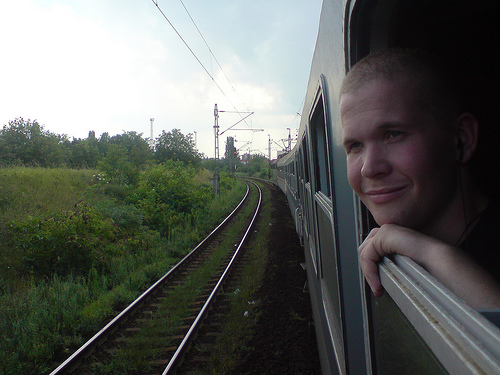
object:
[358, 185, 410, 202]
mouth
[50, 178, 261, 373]
railway line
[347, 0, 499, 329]
frame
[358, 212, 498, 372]
ledge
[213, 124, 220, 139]
part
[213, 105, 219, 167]
pole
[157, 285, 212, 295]
rail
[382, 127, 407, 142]
eye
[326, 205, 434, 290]
an hand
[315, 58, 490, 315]
person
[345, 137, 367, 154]
eye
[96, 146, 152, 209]
bush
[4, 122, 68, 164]
bush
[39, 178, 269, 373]
tracks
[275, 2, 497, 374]
train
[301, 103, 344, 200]
window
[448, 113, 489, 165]
ear